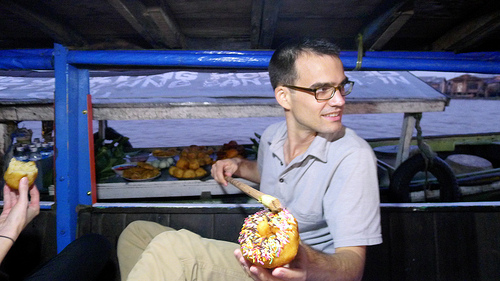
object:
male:
[108, 38, 385, 281]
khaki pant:
[118, 218, 257, 281]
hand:
[209, 158, 238, 187]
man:
[109, 45, 384, 277]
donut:
[236, 200, 303, 265]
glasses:
[283, 80, 354, 101]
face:
[293, 54, 349, 133]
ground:
[403, 125, 469, 180]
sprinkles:
[239, 208, 293, 265]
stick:
[221, 172, 280, 212]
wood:
[240, 180, 257, 200]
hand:
[233, 206, 315, 281]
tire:
[387, 156, 461, 203]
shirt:
[251, 120, 383, 259]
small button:
[278, 176, 283, 182]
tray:
[111, 160, 161, 182]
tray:
[141, 150, 177, 172]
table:
[46, 145, 261, 201]